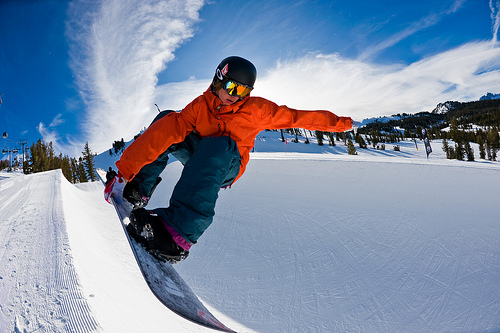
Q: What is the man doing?
A: Snowboarding.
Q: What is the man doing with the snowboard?
A: Grinding on a half pipe.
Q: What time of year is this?
A: Winter.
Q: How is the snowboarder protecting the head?
A: A helmet.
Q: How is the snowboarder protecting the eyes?
A: Goggles.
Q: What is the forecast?
A: Blue skies with white clouds.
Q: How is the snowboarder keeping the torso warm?
A: Winter jacket.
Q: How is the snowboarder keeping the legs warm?
A: Snow pants.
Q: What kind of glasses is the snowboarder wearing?
A: Snow goggles.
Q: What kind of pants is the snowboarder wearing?
A: Blue snowboarding pants.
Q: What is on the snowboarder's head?
A: A helmet.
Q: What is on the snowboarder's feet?
A: Boots.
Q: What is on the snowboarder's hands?
A: Gloves.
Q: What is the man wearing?
A: A jacket.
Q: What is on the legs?
A: Pants.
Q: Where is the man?
A: At a snowboarding event.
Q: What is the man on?
A: A snowboard.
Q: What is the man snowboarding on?
A: A half pipe.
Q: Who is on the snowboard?
A: The man in orange.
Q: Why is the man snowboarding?
A: For sport.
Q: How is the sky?
A: Clear and sunny.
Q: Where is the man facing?
A: The camera.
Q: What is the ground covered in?
A: Snow.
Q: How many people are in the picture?
A: One.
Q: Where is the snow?
A: The ground.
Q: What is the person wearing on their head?
A: A helmet.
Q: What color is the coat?
A: Orange.